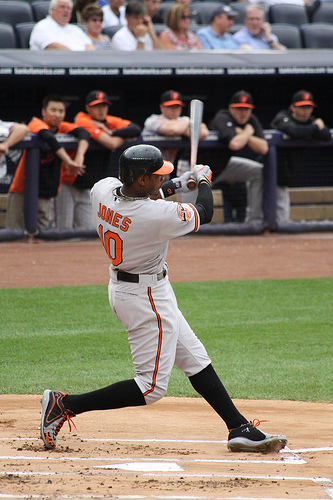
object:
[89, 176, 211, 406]
baseball uniform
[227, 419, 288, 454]
cleat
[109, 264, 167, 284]
belt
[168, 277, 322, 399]
turf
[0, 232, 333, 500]
baseball field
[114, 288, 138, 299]
pocket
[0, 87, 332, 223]
men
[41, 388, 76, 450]
cleat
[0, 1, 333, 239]
bleachers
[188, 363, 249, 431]
sock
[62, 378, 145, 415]
sock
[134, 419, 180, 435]
dirt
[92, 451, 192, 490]
plate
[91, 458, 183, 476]
home plate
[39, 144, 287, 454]
man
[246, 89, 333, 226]
man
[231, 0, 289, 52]
man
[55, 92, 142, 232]
man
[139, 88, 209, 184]
man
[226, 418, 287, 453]
shoe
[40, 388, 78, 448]
shoe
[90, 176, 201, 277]
jersey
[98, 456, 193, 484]
home plate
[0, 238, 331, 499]
baseball field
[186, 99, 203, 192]
bat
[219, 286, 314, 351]
grass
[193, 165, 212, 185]
glove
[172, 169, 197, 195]
glove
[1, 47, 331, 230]
dugout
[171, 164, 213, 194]
gloves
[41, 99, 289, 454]
baseball player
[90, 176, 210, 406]
uniform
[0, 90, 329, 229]
baseball player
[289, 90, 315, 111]
hat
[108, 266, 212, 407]
pants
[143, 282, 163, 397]
stripe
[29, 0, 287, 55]
spectators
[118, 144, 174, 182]
hat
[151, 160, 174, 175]
visor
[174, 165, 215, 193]
man's hands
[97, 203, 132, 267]
writing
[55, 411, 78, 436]
shoe laces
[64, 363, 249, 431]
socks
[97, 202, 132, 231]
letters